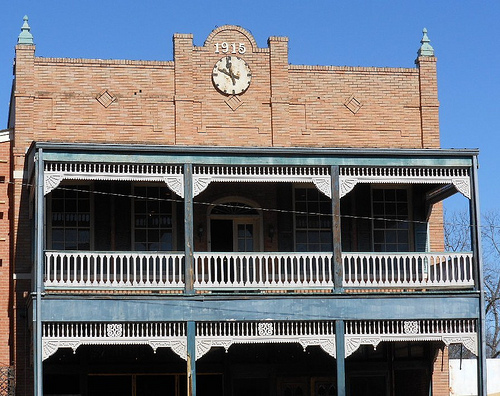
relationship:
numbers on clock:
[214, 40, 254, 54] [206, 49, 257, 94]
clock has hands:
[209, 45, 252, 97] [220, 61, 241, 83]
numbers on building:
[213, 38, 251, 55] [11, 14, 484, 389]